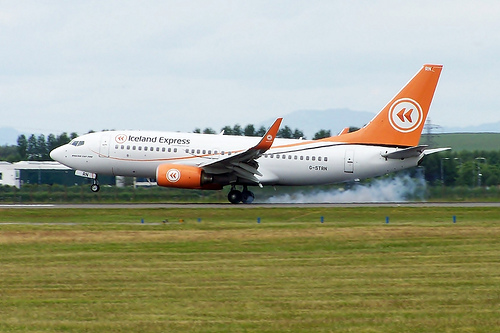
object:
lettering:
[309, 165, 328, 171]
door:
[98, 131, 110, 158]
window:
[173, 148, 177, 153]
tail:
[333, 63, 445, 147]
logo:
[128, 135, 190, 145]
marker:
[385, 216, 390, 223]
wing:
[197, 117, 283, 172]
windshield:
[77, 141, 85, 147]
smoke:
[252, 168, 430, 203]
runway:
[0, 202, 500, 209]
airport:
[49, 63, 452, 204]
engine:
[156, 163, 213, 189]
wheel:
[227, 190, 243, 205]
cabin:
[64, 138, 91, 151]